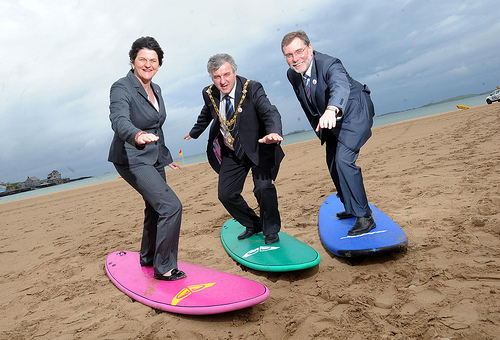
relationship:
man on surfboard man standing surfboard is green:
[184, 55, 284, 246] [219, 216, 322, 282]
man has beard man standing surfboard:
[282, 30, 375, 235] [317, 192, 406, 257]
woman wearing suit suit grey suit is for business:
[107, 36, 188, 280] [108, 72, 186, 281]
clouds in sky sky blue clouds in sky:
[1, 4, 500, 208] [0, 0, 497, 192]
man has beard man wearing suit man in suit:
[282, 30, 375, 235] [184, 55, 284, 246]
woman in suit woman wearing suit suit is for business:
[107, 36, 188, 280] [108, 72, 186, 281]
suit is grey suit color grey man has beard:
[107, 36, 188, 280] [282, 30, 375, 235]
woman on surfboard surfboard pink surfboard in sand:
[107, 36, 188, 280] [103, 249, 268, 318]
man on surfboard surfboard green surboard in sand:
[184, 55, 284, 246] [219, 216, 322, 282]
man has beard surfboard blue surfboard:
[282, 30, 375, 235] [317, 192, 406, 257]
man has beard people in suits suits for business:
[282, 30, 375, 235] [104, 51, 375, 279]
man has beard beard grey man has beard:
[286, 49, 313, 77] [282, 30, 375, 235]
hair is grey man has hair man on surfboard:
[207, 53, 237, 82] [184, 53, 281, 244]